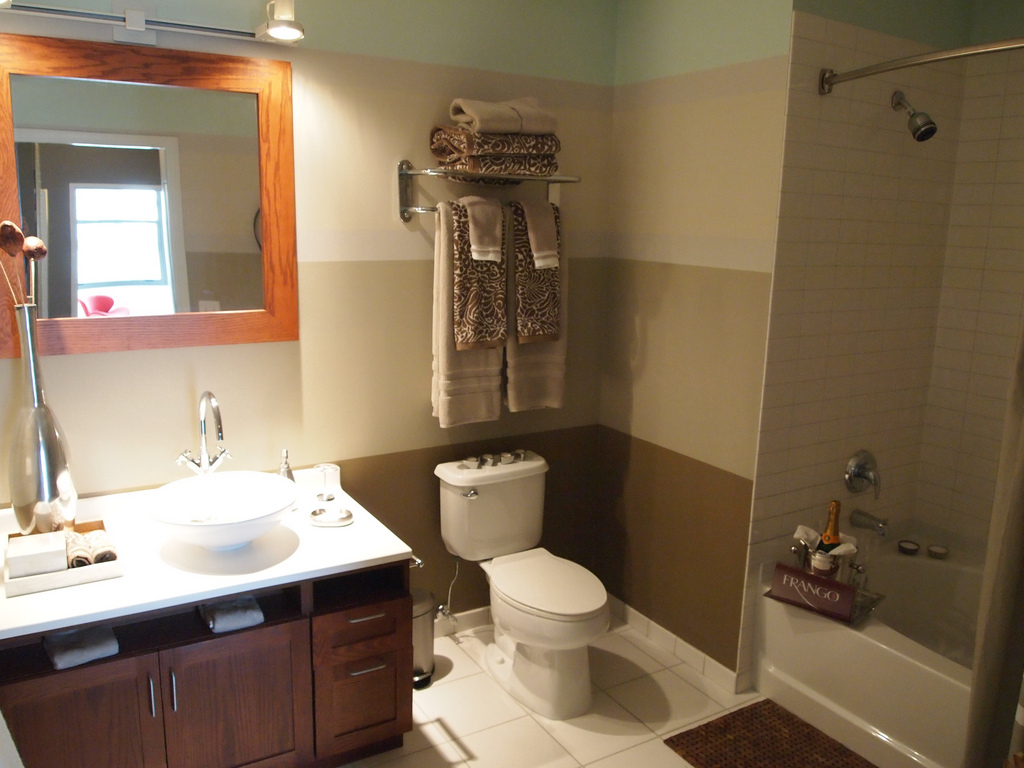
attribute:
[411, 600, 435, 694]
trash — small, metal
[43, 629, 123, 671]
towel — hand